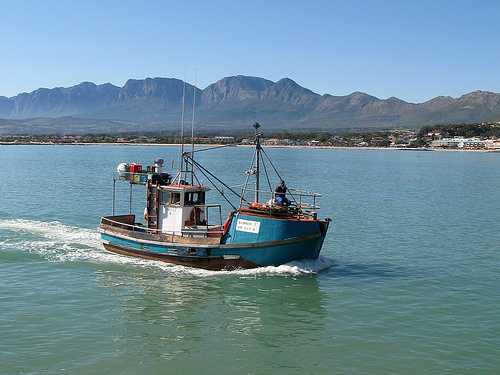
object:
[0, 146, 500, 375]
water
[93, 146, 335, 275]
boat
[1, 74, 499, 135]
mountains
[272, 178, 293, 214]
person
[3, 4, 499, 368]
photo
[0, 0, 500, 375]
sunny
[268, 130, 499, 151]
houses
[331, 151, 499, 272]
no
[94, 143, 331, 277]
sailing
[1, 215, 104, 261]
waves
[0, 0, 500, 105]
sky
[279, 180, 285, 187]
head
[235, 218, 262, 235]
sign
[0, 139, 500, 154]
beach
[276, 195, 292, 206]
shorts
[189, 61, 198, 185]
pole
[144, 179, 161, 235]
ladder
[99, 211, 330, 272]
turquoise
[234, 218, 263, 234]
white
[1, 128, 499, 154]
buildings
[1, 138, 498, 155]
coastline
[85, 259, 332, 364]
reflection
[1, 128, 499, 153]
city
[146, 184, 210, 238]
cabin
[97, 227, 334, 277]
base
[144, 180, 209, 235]
white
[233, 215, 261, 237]
visible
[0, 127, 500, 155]
shore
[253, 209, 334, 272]
bow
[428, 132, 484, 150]
building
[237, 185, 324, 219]
railing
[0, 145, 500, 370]
sea